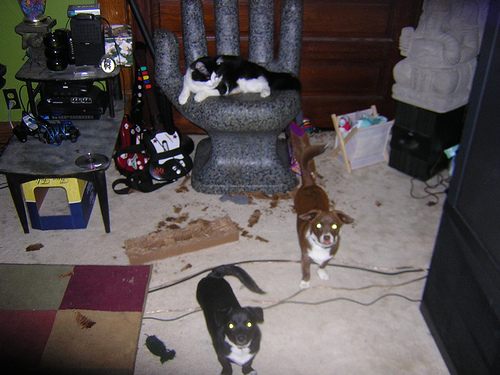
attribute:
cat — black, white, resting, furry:
[177, 53, 301, 108]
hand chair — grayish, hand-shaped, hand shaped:
[152, 1, 305, 197]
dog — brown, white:
[293, 143, 354, 292]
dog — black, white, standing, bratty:
[196, 264, 266, 374]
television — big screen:
[419, 1, 500, 374]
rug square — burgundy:
[58, 264, 152, 312]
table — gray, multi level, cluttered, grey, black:
[1, 63, 131, 234]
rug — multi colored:
[1, 261, 154, 374]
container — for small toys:
[328, 103, 397, 175]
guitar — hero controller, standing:
[135, 49, 196, 181]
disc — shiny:
[74, 152, 111, 171]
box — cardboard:
[21, 177, 97, 230]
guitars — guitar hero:
[113, 40, 195, 181]